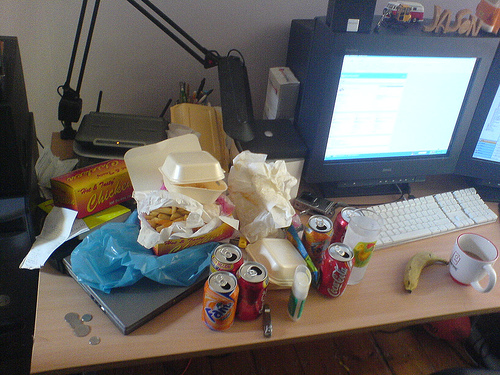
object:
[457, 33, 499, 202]
monitor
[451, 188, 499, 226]
keyboard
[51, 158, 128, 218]
box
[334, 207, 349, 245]
coke soda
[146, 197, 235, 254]
container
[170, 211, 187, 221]
fries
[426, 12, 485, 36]
name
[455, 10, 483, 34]
wood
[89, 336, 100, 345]
coins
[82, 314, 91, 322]
coins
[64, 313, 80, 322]
coins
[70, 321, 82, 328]
coins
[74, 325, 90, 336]
coins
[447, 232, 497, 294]
mug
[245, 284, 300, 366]
clips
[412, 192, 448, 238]
keyboard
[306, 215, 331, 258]
soda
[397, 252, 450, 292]
banana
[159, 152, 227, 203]
container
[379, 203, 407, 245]
keyboard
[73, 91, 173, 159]
router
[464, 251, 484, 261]
coffee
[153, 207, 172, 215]
french fries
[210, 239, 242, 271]
soda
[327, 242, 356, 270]
open coke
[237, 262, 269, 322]
can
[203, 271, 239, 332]
can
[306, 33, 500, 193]
monitor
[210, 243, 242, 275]
can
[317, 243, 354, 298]
can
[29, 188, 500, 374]
desk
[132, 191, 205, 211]
paper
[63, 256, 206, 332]
laptop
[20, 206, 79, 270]
paper